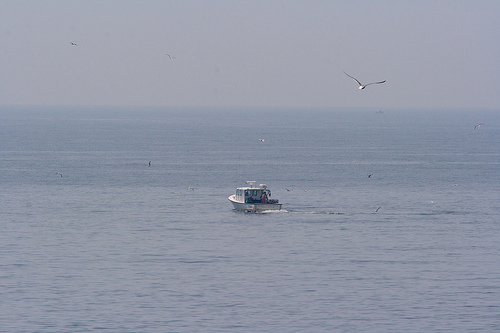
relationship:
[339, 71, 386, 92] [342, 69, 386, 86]
bird has wings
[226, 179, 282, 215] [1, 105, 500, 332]
boat on water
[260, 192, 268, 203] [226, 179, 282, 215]
people on boat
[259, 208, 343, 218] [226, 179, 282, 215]
waves behind boat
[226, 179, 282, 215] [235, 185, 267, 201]
boat has cabin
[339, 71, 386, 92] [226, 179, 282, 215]
bird near boat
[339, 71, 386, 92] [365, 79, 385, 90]
bird has wing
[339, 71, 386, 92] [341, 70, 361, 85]
bird has wing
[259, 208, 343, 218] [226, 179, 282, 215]
waves from boat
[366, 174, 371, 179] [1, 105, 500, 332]
spot on water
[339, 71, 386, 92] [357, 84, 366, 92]
bird has body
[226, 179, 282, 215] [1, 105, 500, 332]
boat heading out to water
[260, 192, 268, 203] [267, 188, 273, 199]
people checking lines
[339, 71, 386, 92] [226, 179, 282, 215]
bird above boat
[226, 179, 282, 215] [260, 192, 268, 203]
boat has people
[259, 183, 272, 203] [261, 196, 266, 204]
people wears pants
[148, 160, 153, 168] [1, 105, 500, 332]
bouys on water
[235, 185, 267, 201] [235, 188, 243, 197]
cabin has windows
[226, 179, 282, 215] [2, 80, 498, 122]
boat on horizon